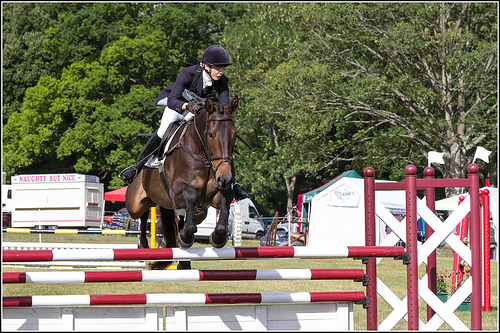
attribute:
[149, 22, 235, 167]
woman — in black, white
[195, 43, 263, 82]
black hat — for riding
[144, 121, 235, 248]
horse — jumping, brown, muscular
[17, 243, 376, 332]
fence — red, white, for horse jumping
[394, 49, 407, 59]
leaves — green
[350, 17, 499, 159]
trees — green, branched, in background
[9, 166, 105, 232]
snack bar — parked, closed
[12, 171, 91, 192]
letters — naughty but nice, red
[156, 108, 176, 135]
pants — white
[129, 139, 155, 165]
boots — leather, black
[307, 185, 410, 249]
tents — white, parked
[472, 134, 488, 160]
flag — white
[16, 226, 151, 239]
pole — black, yellow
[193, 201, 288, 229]
van — parked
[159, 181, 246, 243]
legs — black, bent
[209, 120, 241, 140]
eyes — open